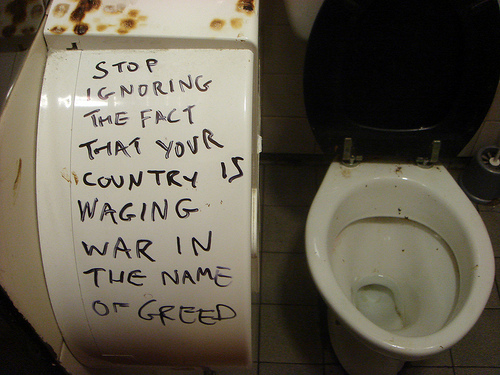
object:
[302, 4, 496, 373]
toilet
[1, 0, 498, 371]
bathroom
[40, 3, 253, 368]
dispenser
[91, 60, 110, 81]
letters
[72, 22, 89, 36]
rust marks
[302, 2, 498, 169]
lid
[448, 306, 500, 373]
tiles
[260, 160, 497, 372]
floor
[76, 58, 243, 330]
politics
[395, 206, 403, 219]
stains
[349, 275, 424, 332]
water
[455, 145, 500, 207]
toilet brush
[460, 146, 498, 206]
case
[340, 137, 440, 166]
hinge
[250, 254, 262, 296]
paper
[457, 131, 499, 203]
corner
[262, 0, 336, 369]
shadow